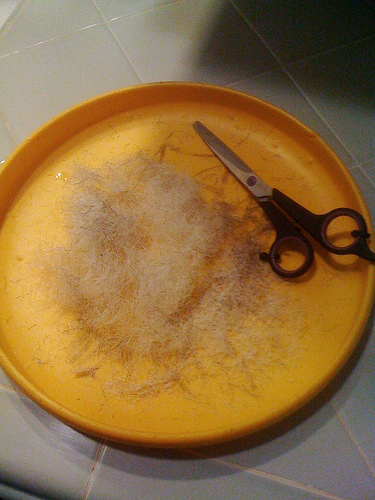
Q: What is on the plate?
A: Hair.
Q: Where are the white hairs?
A: On the plate.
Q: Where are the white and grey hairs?
A: Plate.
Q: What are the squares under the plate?
A: Tiles.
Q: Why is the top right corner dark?
A: Shadow.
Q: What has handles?
A: Scissor.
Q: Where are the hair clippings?
A: Yellow bowl.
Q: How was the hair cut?
A: Scissors.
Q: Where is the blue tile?
A: Surface under yellow bowl.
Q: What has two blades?
A: Scissor.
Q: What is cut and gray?
A: Hair trimmings.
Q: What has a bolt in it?
A: Scissor blades.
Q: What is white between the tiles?
A: Grout.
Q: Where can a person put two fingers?
A: Scissor handles.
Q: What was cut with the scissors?
A: Gray hairs.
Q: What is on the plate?
A: Scissors,.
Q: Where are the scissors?
A: On the plate.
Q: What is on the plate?
A: Hair.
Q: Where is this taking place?
A: Indoors.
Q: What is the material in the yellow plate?
A: Fur.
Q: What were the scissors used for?
A: To trim the fur.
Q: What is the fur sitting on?
A: Yellow plate.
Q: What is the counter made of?
A: Tiles.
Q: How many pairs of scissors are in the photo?
A: One.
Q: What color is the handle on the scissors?
A: Black.